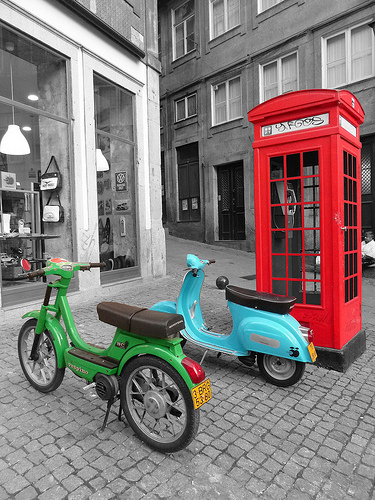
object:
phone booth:
[247, 89, 366, 373]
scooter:
[15, 256, 212, 453]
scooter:
[148, 254, 318, 386]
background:
[0, 1, 375, 499]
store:
[0, 0, 169, 320]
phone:
[271, 180, 296, 240]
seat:
[96, 302, 186, 340]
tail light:
[181, 357, 206, 384]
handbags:
[39, 155, 65, 195]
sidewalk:
[1, 234, 375, 498]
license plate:
[191, 378, 213, 412]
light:
[0, 40, 31, 156]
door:
[217, 161, 246, 241]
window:
[0, 19, 83, 298]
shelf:
[0, 182, 60, 278]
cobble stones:
[0, 235, 375, 499]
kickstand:
[99, 396, 124, 434]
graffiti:
[261, 115, 323, 135]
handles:
[85, 261, 106, 271]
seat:
[225, 285, 298, 316]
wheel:
[118, 355, 200, 454]